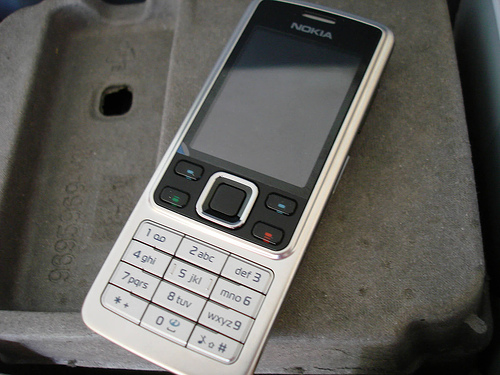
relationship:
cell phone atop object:
[80, 0, 395, 375] [5, 15, 483, 345]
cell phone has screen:
[80, 0, 395, 375] [180, 0, 385, 190]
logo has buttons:
[291, 21, 332, 38] [144, 146, 311, 250]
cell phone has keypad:
[80, 0, 395, 375] [99, 219, 275, 366]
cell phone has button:
[84, 71, 389, 356] [252, 216, 281, 249]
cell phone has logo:
[80, 0, 395, 375] [291, 18, 334, 42]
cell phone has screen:
[80, 0, 395, 375] [210, 39, 310, 175]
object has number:
[18, 113, 138, 330] [48, 177, 89, 282]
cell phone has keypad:
[80, 0, 395, 375] [99, 196, 286, 361]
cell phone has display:
[80, 0, 395, 375] [184, 0, 368, 195]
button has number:
[134, 222, 179, 253] [143, 224, 155, 241]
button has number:
[134, 222, 179, 253] [185, 241, 200, 261]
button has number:
[134, 222, 179, 253] [165, 289, 178, 303]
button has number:
[134, 222, 179, 253] [250, 269, 264, 286]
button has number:
[134, 222, 179, 253] [130, 248, 142, 262]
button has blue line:
[173, 159, 206, 181] [189, 170, 197, 173]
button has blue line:
[262, 194, 299, 215] [276, 197, 283, 210]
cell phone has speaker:
[80, 0, 395, 375] [299, 8, 339, 28]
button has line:
[160, 187, 190, 208] [146, 191, 214, 211]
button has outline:
[185, 166, 265, 235] [188, 167, 268, 236]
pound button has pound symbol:
[186, 320, 245, 364] [214, 339, 229, 355]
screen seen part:
[201, 61, 355, 148] [268, 102, 275, 122]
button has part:
[198, 330, 249, 364] [213, 344, 225, 354]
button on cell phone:
[194, 170, 258, 230] [80, 0, 395, 375]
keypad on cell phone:
[99, 219, 275, 366] [80, 0, 395, 375]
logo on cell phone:
[289, 19, 333, 41] [80, 0, 395, 375]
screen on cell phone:
[174, 0, 384, 200] [80, 0, 395, 375]